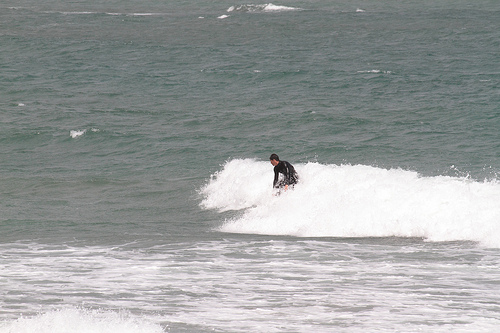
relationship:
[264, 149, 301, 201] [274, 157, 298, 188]
man with wetsuit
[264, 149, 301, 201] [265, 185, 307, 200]
man on surfboard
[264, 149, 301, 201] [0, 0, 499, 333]
man in water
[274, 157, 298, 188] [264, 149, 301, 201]
wetsuit on man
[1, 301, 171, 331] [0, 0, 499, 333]
wave in water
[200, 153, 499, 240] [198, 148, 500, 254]
water splashing from wave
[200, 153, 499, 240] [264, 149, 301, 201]
water around man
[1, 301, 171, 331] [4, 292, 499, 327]
wave coming to shore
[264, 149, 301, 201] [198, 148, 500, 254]
man surfing in wave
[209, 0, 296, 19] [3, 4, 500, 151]
wave in background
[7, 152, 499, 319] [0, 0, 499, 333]
suds in water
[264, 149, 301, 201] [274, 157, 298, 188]
man in wetsuit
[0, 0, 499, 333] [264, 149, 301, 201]
water next to man